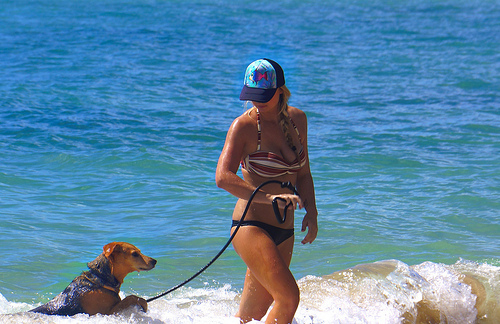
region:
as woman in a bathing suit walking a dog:
[215, 61, 325, 319]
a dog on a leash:
[36, 230, 158, 318]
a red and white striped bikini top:
[245, 111, 321, 188]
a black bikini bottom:
[223, 209, 311, 266]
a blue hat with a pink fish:
[228, 52, 287, 123]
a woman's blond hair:
[269, 75, 311, 163]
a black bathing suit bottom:
[226, 207, 308, 253]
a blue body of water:
[0, 0, 497, 297]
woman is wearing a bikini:
[191, 43, 332, 318]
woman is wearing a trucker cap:
[210, 52, 335, 323]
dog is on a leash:
[17, 239, 167, 323]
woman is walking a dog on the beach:
[30, 36, 350, 323]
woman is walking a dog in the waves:
[25, 44, 330, 322]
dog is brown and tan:
[21, 233, 171, 323]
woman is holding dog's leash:
[15, 47, 330, 322]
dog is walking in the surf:
[20, 226, 163, 321]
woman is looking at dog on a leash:
[37, 56, 332, 321]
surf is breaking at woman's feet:
[2, 246, 496, 323]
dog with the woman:
[42, 229, 178, 322]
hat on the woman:
[236, 56, 283, 99]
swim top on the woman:
[244, 106, 309, 181]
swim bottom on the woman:
[226, 207, 301, 243]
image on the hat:
[246, 68, 269, 90]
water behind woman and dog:
[15, 46, 485, 256]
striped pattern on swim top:
[256, 158, 298, 174]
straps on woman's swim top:
[248, 110, 304, 150]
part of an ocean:
[393, 140, 406, 152]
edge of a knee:
[289, 306, 291, 311]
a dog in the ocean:
[6, 199, 165, 319]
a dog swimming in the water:
[1, 215, 162, 317]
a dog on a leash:
[16, 143, 320, 319]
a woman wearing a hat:
[213, 50, 292, 150]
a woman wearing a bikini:
[180, 39, 340, 288]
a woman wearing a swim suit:
[176, 40, 347, 296]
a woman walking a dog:
[30, 58, 335, 322]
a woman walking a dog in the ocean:
[25, 42, 335, 320]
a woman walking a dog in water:
[19, 38, 341, 321]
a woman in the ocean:
[185, 60, 407, 315]